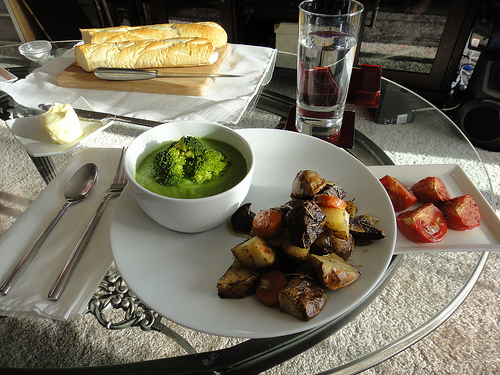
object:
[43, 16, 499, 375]
dishes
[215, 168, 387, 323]
vegatables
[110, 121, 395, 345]
plate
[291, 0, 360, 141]
glass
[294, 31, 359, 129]
water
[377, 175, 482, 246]
tomatoes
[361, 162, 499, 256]
side plate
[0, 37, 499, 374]
table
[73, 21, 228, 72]
bread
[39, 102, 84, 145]
butter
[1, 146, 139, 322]
napkin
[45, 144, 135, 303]
fork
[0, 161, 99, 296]
spoon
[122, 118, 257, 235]
bowl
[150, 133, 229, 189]
broccoli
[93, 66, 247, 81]
knife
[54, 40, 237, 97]
breadboard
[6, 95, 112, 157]
napkin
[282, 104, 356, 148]
coaster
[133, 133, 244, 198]
broccoli soup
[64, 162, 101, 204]
top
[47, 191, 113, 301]
handle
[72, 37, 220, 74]
loaf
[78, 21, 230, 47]
loaf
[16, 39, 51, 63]
container